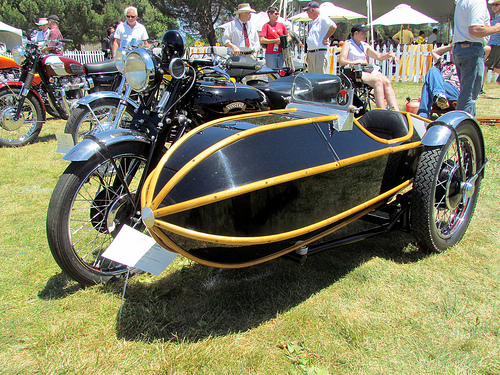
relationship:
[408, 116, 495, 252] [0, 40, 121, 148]
back tire of a motorcycle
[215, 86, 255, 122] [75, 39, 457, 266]
gas tank on motorcycle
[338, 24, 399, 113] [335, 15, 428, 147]
person with shorts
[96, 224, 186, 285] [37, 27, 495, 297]
sign in front of vehicle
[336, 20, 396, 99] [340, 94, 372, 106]
person sitting in wheelchair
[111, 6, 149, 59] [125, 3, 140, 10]
man has hairline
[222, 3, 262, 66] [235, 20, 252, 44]
man wearing tie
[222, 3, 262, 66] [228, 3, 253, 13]
man wearing hat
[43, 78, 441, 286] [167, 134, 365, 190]
motorcycle next to vehicle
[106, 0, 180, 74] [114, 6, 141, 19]
man with glasses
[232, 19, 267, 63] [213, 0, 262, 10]
tie with hat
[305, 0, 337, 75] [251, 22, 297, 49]
man with shirt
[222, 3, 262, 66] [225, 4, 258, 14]
man wearing hat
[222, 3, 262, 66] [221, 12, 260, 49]
man wearing shirt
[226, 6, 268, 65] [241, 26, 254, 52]
man wearing tie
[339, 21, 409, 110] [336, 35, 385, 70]
woman wearing shirt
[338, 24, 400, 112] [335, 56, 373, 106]
woman sitting in chair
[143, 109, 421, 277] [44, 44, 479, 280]
sidecar on motorcycle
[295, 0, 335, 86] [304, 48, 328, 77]
man wearing khakis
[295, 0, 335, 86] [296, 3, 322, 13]
man wearing cap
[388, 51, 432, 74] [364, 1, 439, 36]
table shaded by umbrella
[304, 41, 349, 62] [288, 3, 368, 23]
table shaded by umbrella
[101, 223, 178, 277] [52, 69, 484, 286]
sign in front of motorcycle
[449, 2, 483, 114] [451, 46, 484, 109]
man wearing jeans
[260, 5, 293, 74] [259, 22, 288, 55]
person wearing shirt